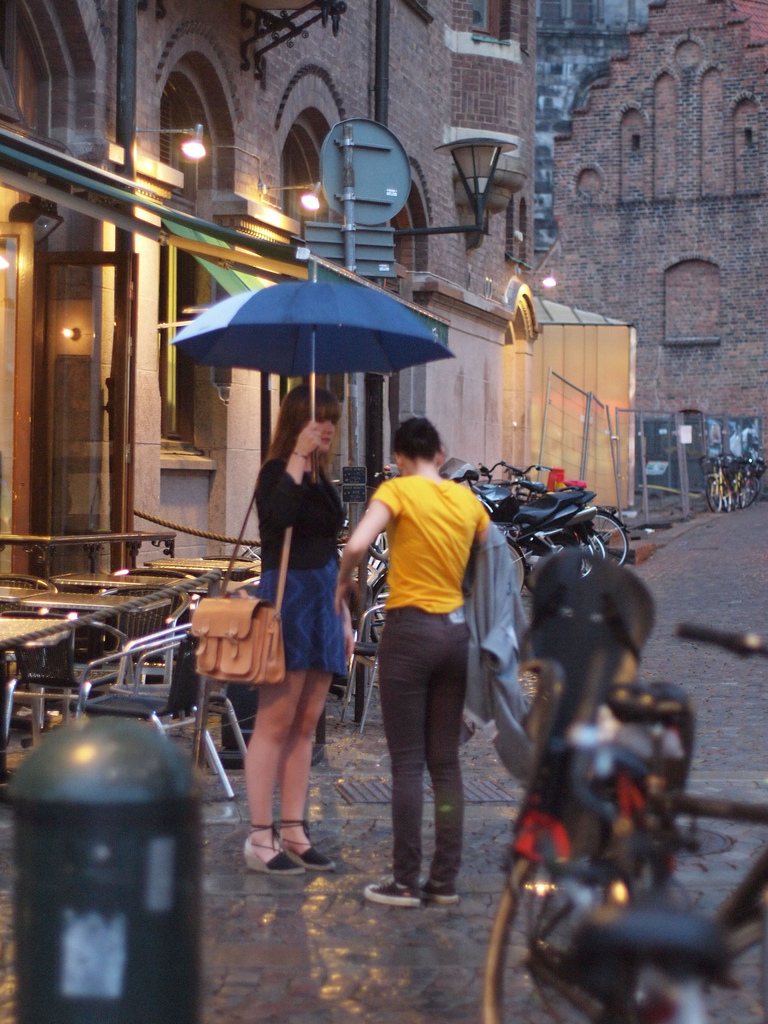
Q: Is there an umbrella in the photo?
A: Yes, there is an umbrella.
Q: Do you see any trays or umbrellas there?
A: Yes, there is an umbrella.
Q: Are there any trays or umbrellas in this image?
A: Yes, there is an umbrella.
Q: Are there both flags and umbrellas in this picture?
A: No, there is an umbrella but no flags.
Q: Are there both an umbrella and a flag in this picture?
A: No, there is an umbrella but no flags.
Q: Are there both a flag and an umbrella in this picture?
A: No, there is an umbrella but no flags.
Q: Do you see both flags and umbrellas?
A: No, there is an umbrella but no flags.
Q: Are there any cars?
A: No, there are no cars.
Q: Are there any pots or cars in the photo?
A: No, there are no cars or pots.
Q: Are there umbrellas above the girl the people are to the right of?
A: Yes, there is an umbrella above the girl.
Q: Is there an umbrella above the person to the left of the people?
A: Yes, there is an umbrella above the girl.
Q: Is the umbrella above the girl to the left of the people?
A: Yes, the umbrella is above the girl.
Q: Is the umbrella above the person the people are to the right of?
A: Yes, the umbrella is above the girl.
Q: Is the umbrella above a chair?
A: No, the umbrella is above the girl.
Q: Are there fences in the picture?
A: Yes, there is a fence.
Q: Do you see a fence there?
A: Yes, there is a fence.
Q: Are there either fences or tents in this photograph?
A: Yes, there is a fence.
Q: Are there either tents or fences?
A: Yes, there is a fence.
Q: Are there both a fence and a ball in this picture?
A: No, there is a fence but no balls.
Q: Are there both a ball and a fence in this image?
A: No, there is a fence but no balls.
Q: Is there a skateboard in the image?
A: No, there are no skateboards.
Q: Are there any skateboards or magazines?
A: No, there are no skateboards or magazines.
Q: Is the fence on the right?
A: Yes, the fence is on the right of the image.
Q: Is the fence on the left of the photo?
A: No, the fence is on the right of the image.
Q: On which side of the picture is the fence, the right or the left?
A: The fence is on the right of the image.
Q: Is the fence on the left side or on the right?
A: The fence is on the right of the image.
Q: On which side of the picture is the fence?
A: The fence is on the right of the image.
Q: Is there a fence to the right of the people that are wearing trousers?
A: Yes, there is a fence to the right of the people.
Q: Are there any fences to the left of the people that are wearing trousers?
A: No, the fence is to the right of the people.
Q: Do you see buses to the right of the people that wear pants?
A: No, there is a fence to the right of the people.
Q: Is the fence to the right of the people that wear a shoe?
A: Yes, the fence is to the right of the people.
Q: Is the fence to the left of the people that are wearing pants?
A: No, the fence is to the right of the people.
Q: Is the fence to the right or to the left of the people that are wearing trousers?
A: The fence is to the right of the people.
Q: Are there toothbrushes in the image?
A: No, there are no toothbrushes.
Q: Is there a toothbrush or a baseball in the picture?
A: No, there are no toothbrushes or baseballs.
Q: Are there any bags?
A: Yes, there is a bag.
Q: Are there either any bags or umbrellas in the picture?
A: Yes, there is a bag.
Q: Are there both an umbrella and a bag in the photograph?
A: Yes, there are both a bag and an umbrella.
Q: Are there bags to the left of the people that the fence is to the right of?
A: Yes, there is a bag to the left of the people.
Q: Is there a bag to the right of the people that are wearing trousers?
A: No, the bag is to the left of the people.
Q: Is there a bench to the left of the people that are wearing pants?
A: No, there is a bag to the left of the people.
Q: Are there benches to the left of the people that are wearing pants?
A: No, there is a bag to the left of the people.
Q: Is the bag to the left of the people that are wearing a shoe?
A: Yes, the bag is to the left of the people.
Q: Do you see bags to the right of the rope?
A: Yes, there is a bag to the right of the rope.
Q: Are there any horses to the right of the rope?
A: No, there is a bag to the right of the rope.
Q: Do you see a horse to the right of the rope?
A: No, there is a bag to the right of the rope.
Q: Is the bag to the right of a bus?
A: No, the bag is to the right of the rope.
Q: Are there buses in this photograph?
A: No, there are no buses.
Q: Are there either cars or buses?
A: No, there are no buses or cars.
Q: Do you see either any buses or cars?
A: No, there are no buses or cars.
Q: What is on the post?
A: The sign is on the post.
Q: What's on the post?
A: The sign is on the post.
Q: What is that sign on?
A: The sign is on the post.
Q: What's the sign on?
A: The sign is on the post.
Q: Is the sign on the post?
A: Yes, the sign is on the post.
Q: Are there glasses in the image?
A: No, there are no glasses.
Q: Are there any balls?
A: No, there are no balls.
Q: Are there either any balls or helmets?
A: No, there are no balls or helmets.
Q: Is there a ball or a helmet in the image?
A: No, there are no balls or helmets.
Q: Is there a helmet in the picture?
A: No, there are no helmets.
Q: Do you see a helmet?
A: No, there are no helmets.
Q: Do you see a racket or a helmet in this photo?
A: No, there are no helmets or rackets.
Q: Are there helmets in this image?
A: No, there are no helmets.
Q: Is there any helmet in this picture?
A: No, there are no helmets.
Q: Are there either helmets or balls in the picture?
A: No, there are no helmets or balls.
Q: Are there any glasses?
A: No, there are no glasses.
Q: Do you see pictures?
A: No, there are no pictures.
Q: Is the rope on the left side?
A: Yes, the rope is on the left of the image.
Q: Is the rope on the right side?
A: No, the rope is on the left of the image.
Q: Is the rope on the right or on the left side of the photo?
A: The rope is on the left of the image.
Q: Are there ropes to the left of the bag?
A: Yes, there is a rope to the left of the bag.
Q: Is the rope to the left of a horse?
A: No, the rope is to the left of a bag.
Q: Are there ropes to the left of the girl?
A: Yes, there is a rope to the left of the girl.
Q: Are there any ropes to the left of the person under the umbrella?
A: Yes, there is a rope to the left of the girl.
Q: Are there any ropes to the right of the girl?
A: No, the rope is to the left of the girl.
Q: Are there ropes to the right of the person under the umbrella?
A: No, the rope is to the left of the girl.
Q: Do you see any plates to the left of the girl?
A: No, there is a rope to the left of the girl.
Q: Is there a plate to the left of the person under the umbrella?
A: No, there is a rope to the left of the girl.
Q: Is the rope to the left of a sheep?
A: No, the rope is to the left of the girl.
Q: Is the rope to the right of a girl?
A: No, the rope is to the left of a girl.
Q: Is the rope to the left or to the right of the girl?
A: The rope is to the left of the girl.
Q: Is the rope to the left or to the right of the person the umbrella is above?
A: The rope is to the left of the girl.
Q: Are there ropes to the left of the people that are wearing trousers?
A: Yes, there is a rope to the left of the people.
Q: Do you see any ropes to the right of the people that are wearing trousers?
A: No, the rope is to the left of the people.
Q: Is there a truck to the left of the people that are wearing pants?
A: No, there is a rope to the left of the people.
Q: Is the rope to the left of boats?
A: No, the rope is to the left of the people.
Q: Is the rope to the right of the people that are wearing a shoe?
A: No, the rope is to the left of the people.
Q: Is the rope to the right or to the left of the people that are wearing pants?
A: The rope is to the left of the people.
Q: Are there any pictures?
A: No, there are no pictures.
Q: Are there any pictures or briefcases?
A: No, there are no pictures or briefcases.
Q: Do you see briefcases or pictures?
A: No, there are no pictures or briefcases.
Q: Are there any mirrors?
A: No, there are no mirrors.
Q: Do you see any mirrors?
A: No, there are no mirrors.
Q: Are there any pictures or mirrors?
A: No, there are no mirrors or pictures.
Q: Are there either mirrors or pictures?
A: No, there are no mirrors or pictures.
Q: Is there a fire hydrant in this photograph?
A: No, there are no fire hydrants.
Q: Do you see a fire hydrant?
A: No, there are no fire hydrants.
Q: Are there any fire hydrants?
A: No, there are no fire hydrants.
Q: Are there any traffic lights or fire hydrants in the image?
A: No, there are no fire hydrants or traffic lights.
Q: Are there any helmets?
A: No, there are no helmets.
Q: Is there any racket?
A: No, there are no rackets.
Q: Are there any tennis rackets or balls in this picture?
A: No, there are no tennis rackets or balls.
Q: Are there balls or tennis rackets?
A: No, there are no tennis rackets or balls.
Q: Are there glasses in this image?
A: No, there are no glasses.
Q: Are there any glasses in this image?
A: No, there are no glasses.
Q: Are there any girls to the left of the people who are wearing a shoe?
A: Yes, there is a girl to the left of the people.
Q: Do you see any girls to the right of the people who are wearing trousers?
A: No, the girl is to the left of the people.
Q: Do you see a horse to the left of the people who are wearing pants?
A: No, there is a girl to the left of the people.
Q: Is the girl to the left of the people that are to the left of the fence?
A: Yes, the girl is to the left of the people.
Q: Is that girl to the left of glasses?
A: No, the girl is to the left of the people.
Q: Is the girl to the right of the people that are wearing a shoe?
A: No, the girl is to the left of the people.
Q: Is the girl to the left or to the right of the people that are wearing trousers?
A: The girl is to the left of the people.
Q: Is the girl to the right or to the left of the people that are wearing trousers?
A: The girl is to the left of the people.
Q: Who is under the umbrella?
A: The girl is under the umbrella.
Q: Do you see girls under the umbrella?
A: Yes, there is a girl under the umbrella.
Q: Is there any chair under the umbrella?
A: No, there is a girl under the umbrella.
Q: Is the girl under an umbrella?
A: Yes, the girl is under an umbrella.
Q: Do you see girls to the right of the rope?
A: Yes, there is a girl to the right of the rope.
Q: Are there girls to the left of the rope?
A: No, the girl is to the right of the rope.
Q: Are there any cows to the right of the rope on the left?
A: No, there is a girl to the right of the rope.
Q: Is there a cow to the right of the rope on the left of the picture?
A: No, there is a girl to the right of the rope.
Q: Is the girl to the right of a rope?
A: Yes, the girl is to the right of a rope.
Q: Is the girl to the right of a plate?
A: No, the girl is to the right of a rope.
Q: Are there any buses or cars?
A: No, there are no buses or cars.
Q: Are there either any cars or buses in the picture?
A: No, there are no buses or cars.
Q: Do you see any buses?
A: No, there are no buses.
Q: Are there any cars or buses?
A: No, there are no buses or cars.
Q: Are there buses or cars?
A: No, there are no buses or cars.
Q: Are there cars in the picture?
A: No, there are no cars.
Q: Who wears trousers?
A: The people wear trousers.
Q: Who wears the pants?
A: The people wear trousers.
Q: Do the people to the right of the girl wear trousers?
A: Yes, the people wear trousers.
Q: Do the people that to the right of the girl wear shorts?
A: No, the people wear trousers.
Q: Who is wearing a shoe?
A: The people are wearing a shoe.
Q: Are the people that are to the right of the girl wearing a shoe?
A: Yes, the people are wearing a shoe.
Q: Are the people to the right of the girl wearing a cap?
A: No, the people are wearing a shoe.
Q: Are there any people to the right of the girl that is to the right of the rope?
A: Yes, there are people to the right of the girl.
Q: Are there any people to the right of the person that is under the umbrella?
A: Yes, there are people to the right of the girl.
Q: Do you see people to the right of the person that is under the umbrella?
A: Yes, there are people to the right of the girl.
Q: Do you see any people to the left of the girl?
A: No, the people are to the right of the girl.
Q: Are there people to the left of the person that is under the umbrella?
A: No, the people are to the right of the girl.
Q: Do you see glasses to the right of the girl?
A: No, there are people to the right of the girl.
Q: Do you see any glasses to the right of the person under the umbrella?
A: No, there are people to the right of the girl.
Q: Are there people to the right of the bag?
A: Yes, there are people to the right of the bag.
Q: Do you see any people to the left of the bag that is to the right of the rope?
A: No, the people are to the right of the bag.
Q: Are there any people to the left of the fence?
A: Yes, there are people to the left of the fence.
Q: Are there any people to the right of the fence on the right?
A: No, the people are to the left of the fence.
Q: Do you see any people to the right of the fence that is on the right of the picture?
A: No, the people are to the left of the fence.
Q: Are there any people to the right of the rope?
A: Yes, there are people to the right of the rope.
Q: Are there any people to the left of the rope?
A: No, the people are to the right of the rope.